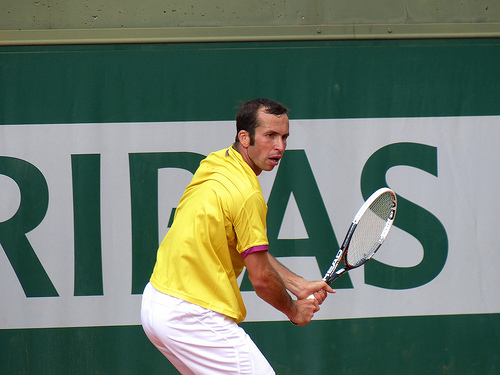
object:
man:
[140, 99, 337, 374]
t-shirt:
[149, 145, 270, 323]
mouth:
[267, 152, 284, 165]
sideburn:
[247, 127, 257, 147]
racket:
[307, 186, 398, 301]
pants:
[140, 281, 276, 375]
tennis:
[367, 220, 368, 235]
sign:
[0, 115, 498, 328]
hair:
[235, 97, 288, 143]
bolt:
[314, 28, 325, 35]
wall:
[3, 2, 497, 371]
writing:
[323, 247, 342, 281]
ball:
[445, 364, 446, 365]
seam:
[187, 310, 258, 375]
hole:
[91, 14, 101, 22]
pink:
[239, 244, 271, 257]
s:
[360, 142, 448, 291]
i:
[70, 152, 108, 298]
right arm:
[235, 190, 295, 318]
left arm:
[267, 252, 308, 296]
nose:
[273, 137, 288, 153]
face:
[251, 113, 290, 171]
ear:
[237, 127, 252, 149]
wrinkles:
[187, 175, 235, 197]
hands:
[291, 296, 321, 325]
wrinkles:
[166, 330, 234, 352]